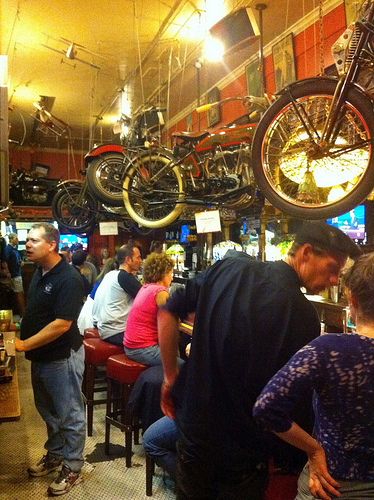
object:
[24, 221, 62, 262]
head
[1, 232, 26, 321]
man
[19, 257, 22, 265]
beer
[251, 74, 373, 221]
wheel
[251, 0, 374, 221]
bike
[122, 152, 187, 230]
tire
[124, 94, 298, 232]
motor bike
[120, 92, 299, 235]
motorcycle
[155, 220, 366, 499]
man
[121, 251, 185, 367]
woman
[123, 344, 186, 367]
blue jeans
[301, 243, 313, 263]
ear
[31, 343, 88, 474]
jeans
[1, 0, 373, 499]
bar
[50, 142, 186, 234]
motorcycle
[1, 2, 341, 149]
ceiling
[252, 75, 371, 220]
tire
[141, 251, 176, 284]
hair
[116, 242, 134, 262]
hair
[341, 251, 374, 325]
hair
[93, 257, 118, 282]
hair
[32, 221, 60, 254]
hair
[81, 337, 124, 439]
stool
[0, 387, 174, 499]
flooring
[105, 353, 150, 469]
stool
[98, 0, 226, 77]
ground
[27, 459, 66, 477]
shoe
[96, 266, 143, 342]
shirt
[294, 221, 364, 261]
hat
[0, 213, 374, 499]
people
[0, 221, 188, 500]
woman's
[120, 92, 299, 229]
bicycle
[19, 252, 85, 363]
shirt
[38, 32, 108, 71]
airplane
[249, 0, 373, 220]
motorcycle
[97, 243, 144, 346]
man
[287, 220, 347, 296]
head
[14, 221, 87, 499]
man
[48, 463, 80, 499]
shoe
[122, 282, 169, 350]
tank top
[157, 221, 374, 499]
woman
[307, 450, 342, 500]
hand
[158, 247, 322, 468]
shirt